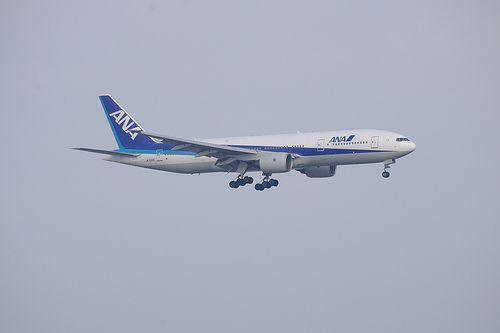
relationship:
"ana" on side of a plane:
[328, 135, 348, 143] [68, 93, 418, 192]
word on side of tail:
[110, 109, 143, 141] [99, 94, 155, 146]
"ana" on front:
[328, 135, 348, 143] [327, 128, 418, 166]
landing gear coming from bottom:
[380, 170, 392, 180] [139, 157, 402, 177]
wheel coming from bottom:
[271, 177, 279, 187] [139, 157, 402, 177]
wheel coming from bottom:
[262, 180, 271, 189] [139, 157, 402, 177]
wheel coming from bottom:
[246, 175, 255, 184] [139, 157, 402, 177]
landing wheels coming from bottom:
[227, 180, 241, 190] [139, 157, 402, 177]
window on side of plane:
[364, 139, 370, 147] [68, 93, 418, 192]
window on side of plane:
[331, 142, 335, 147] [68, 93, 418, 192]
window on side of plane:
[339, 140, 344, 148] [68, 93, 418, 192]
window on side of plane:
[296, 143, 302, 150] [68, 93, 418, 192]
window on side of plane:
[353, 139, 359, 145] [68, 93, 418, 192]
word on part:
[110, 109, 143, 141] [99, 94, 155, 146]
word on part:
[328, 135, 348, 143] [329, 130, 360, 165]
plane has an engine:
[68, 93, 418, 192] [302, 165, 339, 177]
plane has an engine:
[68, 93, 418, 192] [257, 152, 294, 174]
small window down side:
[364, 139, 370, 147] [262, 131, 373, 164]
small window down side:
[331, 140, 337, 146] [262, 131, 373, 164]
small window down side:
[300, 141, 307, 150] [262, 131, 373, 164]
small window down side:
[290, 144, 297, 150] [262, 131, 373, 164]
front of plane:
[327, 128, 418, 166] [68, 93, 418, 192]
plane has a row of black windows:
[68, 93, 418, 192] [331, 140, 369, 147]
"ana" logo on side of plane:
[328, 135, 348, 143] [68, 93, 418, 192]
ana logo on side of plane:
[328, 135, 348, 143] [68, 93, 418, 192]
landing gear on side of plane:
[380, 170, 392, 180] [68, 93, 418, 192]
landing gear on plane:
[380, 170, 392, 180] [68, 93, 418, 192]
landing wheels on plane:
[228, 175, 256, 189] [68, 93, 418, 192]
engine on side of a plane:
[302, 165, 339, 177] [68, 93, 418, 192]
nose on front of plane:
[406, 137, 419, 157] [68, 93, 418, 192]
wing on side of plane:
[136, 131, 260, 157] [68, 93, 418, 192]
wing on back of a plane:
[136, 131, 260, 157] [68, 93, 418, 192]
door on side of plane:
[315, 137, 325, 153] [68, 93, 418, 192]